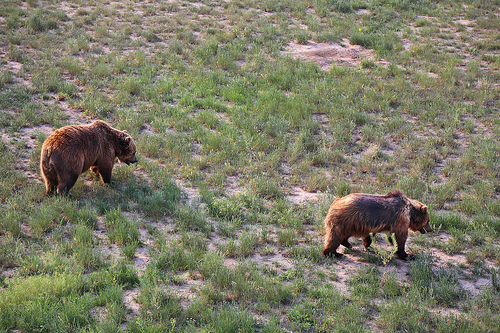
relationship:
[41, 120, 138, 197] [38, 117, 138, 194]
bear on bear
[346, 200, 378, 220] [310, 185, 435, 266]
fur on bear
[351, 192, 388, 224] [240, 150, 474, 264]
fur on bear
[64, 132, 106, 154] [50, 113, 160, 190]
brown fur on bear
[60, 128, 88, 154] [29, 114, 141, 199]
brown fur on bear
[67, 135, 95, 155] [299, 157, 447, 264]
brown fur on bear